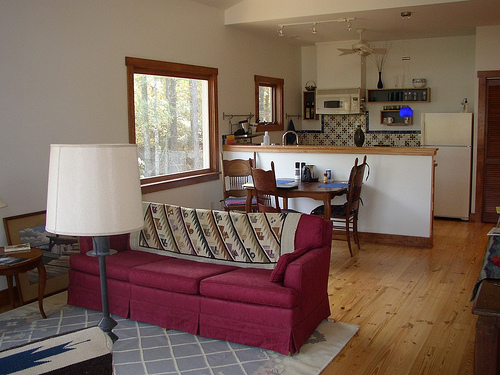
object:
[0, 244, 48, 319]
end table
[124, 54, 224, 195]
toilet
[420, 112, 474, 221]
refrigerator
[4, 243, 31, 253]
book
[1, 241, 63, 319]
table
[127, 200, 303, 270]
blanket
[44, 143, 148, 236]
lamp shade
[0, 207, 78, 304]
picture frame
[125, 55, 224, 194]
window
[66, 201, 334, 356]
couch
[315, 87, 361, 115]
microwave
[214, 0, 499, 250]
kitchen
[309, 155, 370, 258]
chair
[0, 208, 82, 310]
painting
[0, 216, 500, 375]
floor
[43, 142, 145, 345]
lamp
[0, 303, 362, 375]
rug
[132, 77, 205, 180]
trees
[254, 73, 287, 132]
window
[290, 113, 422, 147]
backsplash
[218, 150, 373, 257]
dining area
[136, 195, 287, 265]
pattern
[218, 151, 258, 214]
brown chair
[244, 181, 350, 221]
table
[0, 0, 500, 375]
house